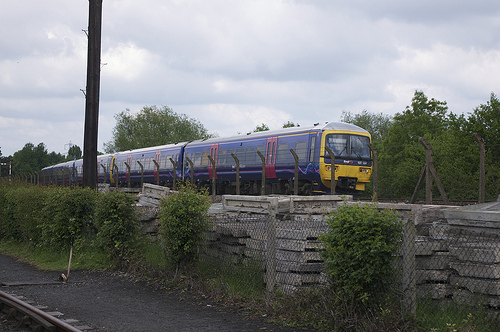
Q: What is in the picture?
A: A subway train.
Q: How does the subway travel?
A: On tracks.